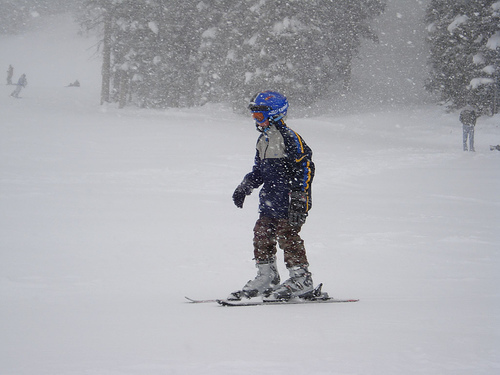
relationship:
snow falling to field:
[371, 20, 431, 98] [0, 96, 497, 365]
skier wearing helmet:
[223, 87, 325, 309] [248, 83, 292, 124]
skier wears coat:
[223, 87, 325, 309] [238, 120, 325, 226]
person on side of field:
[456, 98, 484, 151] [0, 96, 497, 365]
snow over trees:
[441, 13, 472, 37] [103, 0, 380, 109]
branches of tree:
[430, 10, 498, 40] [424, 2, 499, 110]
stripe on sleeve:
[290, 131, 314, 199] [282, 132, 320, 213]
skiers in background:
[6, 59, 34, 109] [4, 57, 103, 61]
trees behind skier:
[103, 0, 380, 109] [223, 87, 325, 309]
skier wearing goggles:
[223, 87, 325, 309] [248, 103, 291, 118]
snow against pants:
[371, 20, 431, 98] [250, 192, 316, 266]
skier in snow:
[223, 87, 325, 309] [104, 219, 461, 352]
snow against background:
[371, 20, 431, 98] [360, 71, 426, 76]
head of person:
[462, 101, 476, 112] [456, 98, 484, 151]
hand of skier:
[231, 183, 249, 210] [223, 87, 325, 309]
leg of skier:
[272, 213, 317, 290] [223, 87, 325, 309]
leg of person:
[272, 213, 317, 290] [456, 98, 484, 151]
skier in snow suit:
[223, 87, 325, 309] [235, 127, 327, 275]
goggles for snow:
[248, 103, 291, 118] [371, 20, 431, 98]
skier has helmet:
[223, 87, 325, 309] [248, 83, 292, 124]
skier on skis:
[223, 87, 325, 309] [175, 286, 361, 311]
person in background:
[456, 98, 484, 151] [4, 57, 103, 61]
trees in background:
[103, 0, 380, 109] [360, 71, 426, 76]